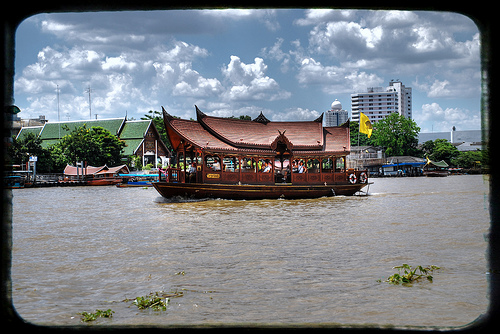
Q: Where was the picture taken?
A: Lake.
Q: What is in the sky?
A: It's clouds.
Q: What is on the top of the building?
A: A green roof.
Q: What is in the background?
A: A tall building.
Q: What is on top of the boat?
A: A roof.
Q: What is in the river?
A: A brown boat.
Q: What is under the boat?
A: It's water.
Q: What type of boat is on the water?
A: A pagoda.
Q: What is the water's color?
A: It's brown.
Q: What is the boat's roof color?
A: It's brown.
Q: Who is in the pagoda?
A: Its people.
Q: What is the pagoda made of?
A: Out of wood.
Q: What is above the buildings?
A: The sky.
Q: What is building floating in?
A: Body of water.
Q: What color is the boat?
A: Brown.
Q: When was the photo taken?
A: Daytime.